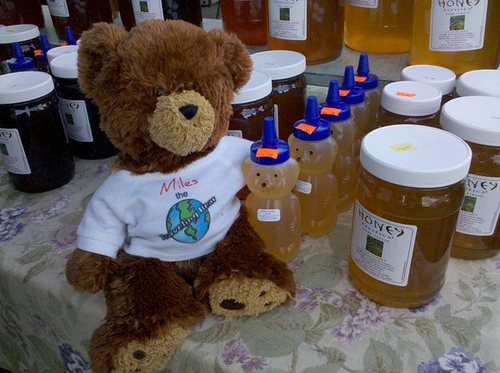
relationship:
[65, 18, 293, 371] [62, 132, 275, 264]
bear in shirt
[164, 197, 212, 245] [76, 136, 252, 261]
globe on shirt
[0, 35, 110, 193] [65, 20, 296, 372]
honey behind bear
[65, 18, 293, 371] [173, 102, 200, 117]
bear has nose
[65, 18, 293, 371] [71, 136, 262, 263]
bear wearing shirt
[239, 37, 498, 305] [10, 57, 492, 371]
honey on table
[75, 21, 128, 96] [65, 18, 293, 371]
ear on bear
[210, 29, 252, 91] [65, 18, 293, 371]
ear on bear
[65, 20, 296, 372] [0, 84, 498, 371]
bear on table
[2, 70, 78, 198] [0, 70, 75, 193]
honey in honey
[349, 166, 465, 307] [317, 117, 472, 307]
honey in jar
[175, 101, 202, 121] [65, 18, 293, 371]
nose on bear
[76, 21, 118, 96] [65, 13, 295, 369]
ear on teddy bear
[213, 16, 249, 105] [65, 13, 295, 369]
ear bear on teddy bear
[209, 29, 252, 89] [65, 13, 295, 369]
ear on teddy bear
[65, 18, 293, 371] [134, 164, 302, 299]
bear wearing shirt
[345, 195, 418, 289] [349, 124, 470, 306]
white label on honey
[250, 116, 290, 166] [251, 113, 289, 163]
lid on lid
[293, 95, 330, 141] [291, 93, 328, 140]
lid on lid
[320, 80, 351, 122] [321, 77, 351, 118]
lid on lid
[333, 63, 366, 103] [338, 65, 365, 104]
squeeze top on squeeze top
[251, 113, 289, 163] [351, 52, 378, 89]
lid on lid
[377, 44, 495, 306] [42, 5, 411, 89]
jars on shelf